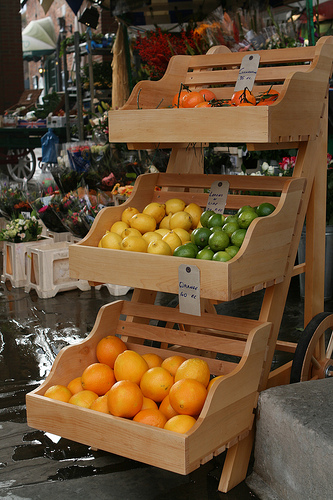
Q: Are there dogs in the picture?
A: No, there are no dogs.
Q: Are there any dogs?
A: No, there are no dogs.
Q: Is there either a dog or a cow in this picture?
A: No, there are no dogs or cows.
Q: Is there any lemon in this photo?
A: Yes, there are lemons.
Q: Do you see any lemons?
A: Yes, there are lemons.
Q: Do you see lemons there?
A: Yes, there are lemons.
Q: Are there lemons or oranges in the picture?
A: Yes, there are lemons.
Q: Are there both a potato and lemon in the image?
A: No, there are lemons but no potatoes.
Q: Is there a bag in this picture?
A: No, there are no bags.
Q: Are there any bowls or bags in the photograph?
A: No, there are no bags or bowls.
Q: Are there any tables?
A: No, there are no tables.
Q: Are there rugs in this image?
A: No, there are no rugs.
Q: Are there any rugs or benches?
A: No, there are no rugs or benches.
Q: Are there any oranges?
A: Yes, there are oranges.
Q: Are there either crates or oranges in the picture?
A: Yes, there are oranges.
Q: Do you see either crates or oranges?
A: Yes, there are oranges.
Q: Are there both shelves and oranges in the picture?
A: Yes, there are both oranges and a shelf.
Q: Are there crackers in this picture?
A: No, there are no crackers.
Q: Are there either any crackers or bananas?
A: No, there are no crackers or bananas.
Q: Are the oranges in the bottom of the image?
A: Yes, the oranges are in the bottom of the image.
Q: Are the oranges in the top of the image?
A: No, the oranges are in the bottom of the image.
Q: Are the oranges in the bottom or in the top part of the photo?
A: The oranges are in the bottom of the image.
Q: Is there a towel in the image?
A: No, there are no towels.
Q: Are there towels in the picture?
A: No, there are no towels.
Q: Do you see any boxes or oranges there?
A: Yes, there are oranges.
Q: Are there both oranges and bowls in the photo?
A: No, there are oranges but no bowls.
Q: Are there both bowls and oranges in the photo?
A: No, there are oranges but no bowls.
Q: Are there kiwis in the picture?
A: No, there are no kiwis.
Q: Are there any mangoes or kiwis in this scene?
A: No, there are no kiwis or mangoes.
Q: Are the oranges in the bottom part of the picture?
A: Yes, the oranges are in the bottom of the image.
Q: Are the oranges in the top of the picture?
A: No, the oranges are in the bottom of the image.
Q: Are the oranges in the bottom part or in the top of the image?
A: The oranges are in the bottom of the image.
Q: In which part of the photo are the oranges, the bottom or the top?
A: The oranges are in the bottom of the image.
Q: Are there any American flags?
A: No, there are no American flags.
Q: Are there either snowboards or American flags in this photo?
A: No, there are no American flags or snowboards.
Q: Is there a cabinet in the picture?
A: No, there are no cabinets.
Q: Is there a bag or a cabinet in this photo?
A: No, there are no cabinets or bags.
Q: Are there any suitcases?
A: No, there are no suitcases.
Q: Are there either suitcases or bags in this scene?
A: No, there are no suitcases or bags.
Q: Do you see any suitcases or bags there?
A: No, there are no suitcases or bags.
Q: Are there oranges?
A: Yes, there are oranges.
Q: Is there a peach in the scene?
A: No, there are no peaches.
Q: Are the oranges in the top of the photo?
A: No, the oranges are in the bottom of the image.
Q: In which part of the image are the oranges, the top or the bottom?
A: The oranges are in the bottom of the image.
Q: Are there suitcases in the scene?
A: No, there are no suitcases.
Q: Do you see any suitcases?
A: No, there are no suitcases.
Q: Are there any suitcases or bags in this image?
A: No, there are no suitcases or bags.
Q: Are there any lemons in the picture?
A: Yes, there are lemons.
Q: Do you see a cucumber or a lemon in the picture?
A: Yes, there are lemons.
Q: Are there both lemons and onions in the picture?
A: No, there are lemons but no onions.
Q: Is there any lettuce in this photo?
A: No, there is no lettuce.